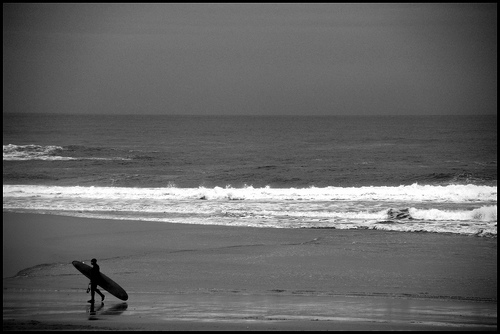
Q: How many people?
A: 1.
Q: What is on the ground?
A: Sand.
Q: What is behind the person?
A: Water.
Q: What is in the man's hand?
A: Surfboard.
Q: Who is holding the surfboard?
A: The man.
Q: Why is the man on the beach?
A: To surf.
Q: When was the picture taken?
A: Daytime.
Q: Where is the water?
A: Behind the man.